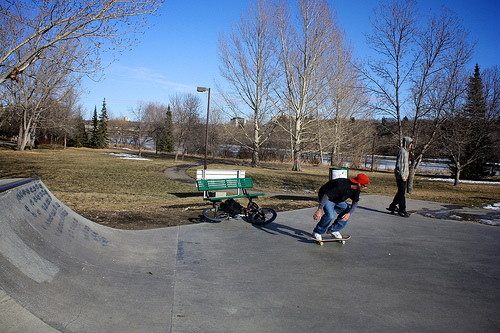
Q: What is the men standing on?
A: Skateboards.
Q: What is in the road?
A: Trees.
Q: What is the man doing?
A: Skating.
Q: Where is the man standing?
A: Skateboard.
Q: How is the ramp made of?
A: Cement.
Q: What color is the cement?
A: Gray.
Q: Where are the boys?
A: On the cement.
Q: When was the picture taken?
A: In the daytime.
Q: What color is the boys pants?
A: Blue and black.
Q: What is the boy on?
A: A skateboard.